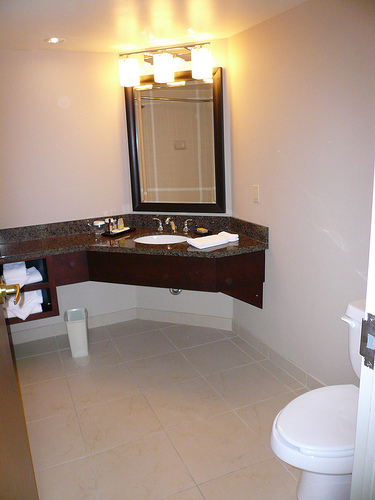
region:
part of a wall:
[298, 88, 351, 127]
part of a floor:
[147, 449, 192, 490]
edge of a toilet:
[277, 444, 310, 474]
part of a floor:
[77, 425, 94, 452]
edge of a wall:
[260, 345, 285, 366]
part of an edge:
[351, 445, 365, 481]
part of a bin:
[64, 291, 92, 347]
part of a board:
[164, 267, 196, 292]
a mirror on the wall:
[115, 65, 229, 212]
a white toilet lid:
[272, 382, 361, 457]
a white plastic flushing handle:
[335, 313, 358, 329]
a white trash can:
[60, 302, 96, 360]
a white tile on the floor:
[73, 392, 167, 461]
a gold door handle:
[0, 279, 23, 311]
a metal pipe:
[168, 285, 181, 298]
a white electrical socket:
[247, 182, 262, 202]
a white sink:
[131, 230, 191, 248]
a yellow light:
[113, 52, 141, 94]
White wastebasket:
[59, 301, 94, 361]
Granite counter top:
[0, 212, 270, 260]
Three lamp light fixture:
[109, 38, 229, 86]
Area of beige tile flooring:
[33, 362, 231, 493]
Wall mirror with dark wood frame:
[117, 65, 228, 214]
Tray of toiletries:
[102, 215, 137, 239]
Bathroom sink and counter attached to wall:
[4, 211, 273, 325]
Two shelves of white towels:
[0, 260, 61, 320]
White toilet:
[265, 296, 362, 498]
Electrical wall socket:
[245, 182, 267, 206]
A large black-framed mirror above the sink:
[115, 68, 226, 213]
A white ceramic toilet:
[268, 298, 368, 498]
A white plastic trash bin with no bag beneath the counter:
[62, 306, 89, 356]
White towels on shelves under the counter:
[0, 255, 47, 321]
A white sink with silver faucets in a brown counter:
[136, 215, 194, 248]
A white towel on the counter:
[184, 230, 239, 248]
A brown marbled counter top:
[0, 212, 270, 307]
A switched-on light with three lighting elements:
[115, 43, 215, 86]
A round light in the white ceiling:
[41, 33, 63, 44]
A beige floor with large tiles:
[10, 306, 326, 498]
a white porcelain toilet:
[268, 285, 371, 495]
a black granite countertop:
[3, 215, 272, 263]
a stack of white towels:
[4, 258, 53, 291]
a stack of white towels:
[3, 292, 44, 319]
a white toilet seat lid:
[275, 378, 361, 458]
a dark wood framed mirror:
[125, 91, 224, 213]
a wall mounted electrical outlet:
[248, 178, 262, 208]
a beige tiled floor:
[13, 320, 305, 495]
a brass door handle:
[0, 276, 22, 309]